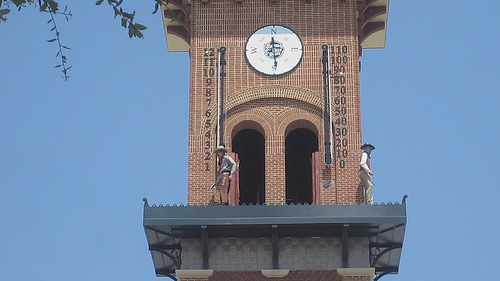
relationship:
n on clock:
[265, 26, 280, 36] [242, 17, 304, 78]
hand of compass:
[270, 36, 277, 68] [244, 22, 304, 77]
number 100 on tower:
[329, 52, 349, 64] [180, 15, 372, 210]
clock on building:
[242, 25, 302, 77] [118, 10, 449, 274]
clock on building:
[235, 17, 312, 94] [129, 0, 461, 277]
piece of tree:
[40, 25, 80, 93] [0, 0, 182, 81]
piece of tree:
[119, 18, 159, 41] [0, 0, 182, 81]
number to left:
[202, 150, 214, 160] [192, 41, 234, 192]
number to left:
[201, 128, 212, 140] [192, 41, 234, 192]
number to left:
[203, 105, 215, 120] [192, 41, 234, 192]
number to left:
[201, 87, 216, 98] [192, 41, 234, 192]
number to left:
[204, 65, 216, 77] [192, 41, 234, 192]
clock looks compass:
[242, 25, 302, 77] [241, 22, 304, 83]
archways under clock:
[226, 114, 324, 204] [227, 18, 339, 111]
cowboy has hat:
[210, 144, 237, 202] [212, 144, 226, 154]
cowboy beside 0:
[357, 139, 373, 206] [339, 161, 346, 170]